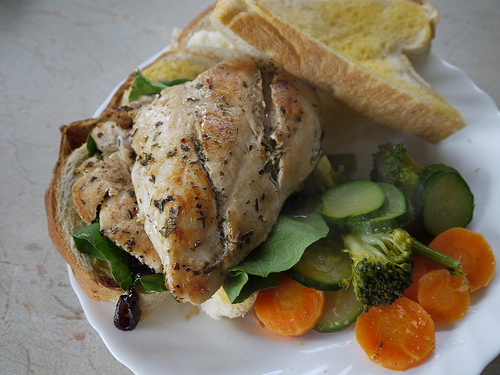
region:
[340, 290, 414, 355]
carrots on a plate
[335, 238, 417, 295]
broccoli on a plate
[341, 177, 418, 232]
cucumbers on a plate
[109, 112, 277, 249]
chicken breast on a plate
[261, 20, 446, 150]
slice on bread on a plate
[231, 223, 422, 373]
vegetables on a white plate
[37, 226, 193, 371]
white plate on a table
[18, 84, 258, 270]
chicken breast on a slice of bread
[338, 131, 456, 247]
zucchini on a plate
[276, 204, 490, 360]
cooked vegetables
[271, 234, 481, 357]
A portion of cooked carrots.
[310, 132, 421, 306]
A few pieces of broccoli.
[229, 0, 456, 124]
Buttered toast on plate.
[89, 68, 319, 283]
Seasoned pan fried chicken.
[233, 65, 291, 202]
A large cut in chicken.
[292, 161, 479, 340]
Zucchini slices on the side.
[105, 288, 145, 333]
A single cranberry.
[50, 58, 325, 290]
Chicken is on lettuce and bread.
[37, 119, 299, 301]
Bread is beneath chicken.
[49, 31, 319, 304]
Buttered toast underneath chicken.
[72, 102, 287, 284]
light brown chicken on plate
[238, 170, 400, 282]
green leafy lettuce on plate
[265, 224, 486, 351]
orange carrots on plate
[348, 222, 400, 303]
light green broccoli next to tomatoes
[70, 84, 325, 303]
chicken breast is seasoned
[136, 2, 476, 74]
buttered bread with chicken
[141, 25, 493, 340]
food on white plate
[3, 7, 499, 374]
plate on light tan background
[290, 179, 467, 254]
green cucumber on plate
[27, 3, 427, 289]
chicken sandwich with vegetables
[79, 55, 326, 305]
the chicken has herbs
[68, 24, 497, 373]
the plate is white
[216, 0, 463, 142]
the bread has butter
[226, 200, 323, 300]
the lettuce is green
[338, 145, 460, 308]
the broccoli is green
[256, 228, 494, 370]
the carrots are orange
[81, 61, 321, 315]
the chicken breast is on bread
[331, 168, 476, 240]
the cucumbers are sliced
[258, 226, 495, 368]
the carrots are sliced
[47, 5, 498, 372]
the plate has food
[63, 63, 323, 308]
it was an animal. i think, a bird. now it has thyme on it.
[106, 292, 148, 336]
what? an olive slice, i think.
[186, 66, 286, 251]
looks like sutures. just cuts in the meat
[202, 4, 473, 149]
white, likely a sourdough, bread with yellow butter on it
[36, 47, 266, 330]
another piece of lightly toasted bread, this one load-bearing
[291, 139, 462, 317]
florets, three. & one possible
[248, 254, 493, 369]
cooked carrots w/ something that looks like salt on them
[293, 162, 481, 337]
steamed zucchini squash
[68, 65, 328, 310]
dark green leaves beneath the spiced ex-animal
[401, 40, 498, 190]
fluttery plate edge